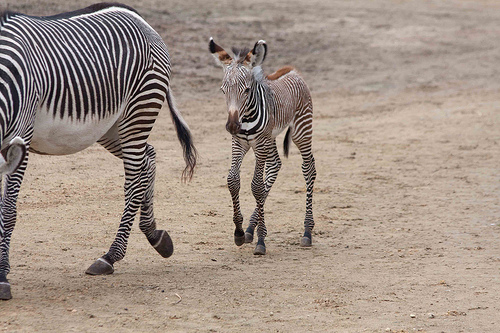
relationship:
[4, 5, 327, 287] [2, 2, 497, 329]
zebras on gravel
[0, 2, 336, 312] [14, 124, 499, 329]
zebras run along gravel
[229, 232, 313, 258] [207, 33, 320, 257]
hooves on baby zebra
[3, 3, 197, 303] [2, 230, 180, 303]
adult zebra has hooves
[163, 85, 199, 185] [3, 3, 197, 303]
tail on zebra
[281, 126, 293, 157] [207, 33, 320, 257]
tail on baby zebra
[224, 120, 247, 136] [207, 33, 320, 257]
black nose on zebra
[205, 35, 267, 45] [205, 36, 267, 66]
white tips on ears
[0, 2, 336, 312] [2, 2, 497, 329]
zebras in wild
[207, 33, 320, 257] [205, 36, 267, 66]
baby zebra has ears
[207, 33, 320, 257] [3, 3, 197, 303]
baby zebra with mother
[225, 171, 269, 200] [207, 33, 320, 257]
knees on baby zebra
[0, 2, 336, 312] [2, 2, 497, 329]
zebras in natural environment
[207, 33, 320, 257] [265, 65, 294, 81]
young zebra has brown hair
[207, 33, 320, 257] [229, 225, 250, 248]
baby zebra has front hoof up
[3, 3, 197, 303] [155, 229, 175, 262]
adult zebra has back hoof up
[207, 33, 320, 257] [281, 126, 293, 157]
baby zebra has short tail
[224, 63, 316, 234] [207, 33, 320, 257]
many stripes on baby zebra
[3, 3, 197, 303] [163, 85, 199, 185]
zebra swishing tail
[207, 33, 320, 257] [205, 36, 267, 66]
zebra has alert ears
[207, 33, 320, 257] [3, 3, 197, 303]
zebra following zebra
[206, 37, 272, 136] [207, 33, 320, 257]
face on baby zebra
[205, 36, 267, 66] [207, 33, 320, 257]
ears on zebra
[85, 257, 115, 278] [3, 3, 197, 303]
hoof on zebra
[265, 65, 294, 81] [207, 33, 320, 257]
brown fur on baby zebra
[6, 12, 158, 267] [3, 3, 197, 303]
stripe pattern on zebra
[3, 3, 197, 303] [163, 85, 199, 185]
zebra has tail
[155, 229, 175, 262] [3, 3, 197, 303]
raised left hoof on zebra